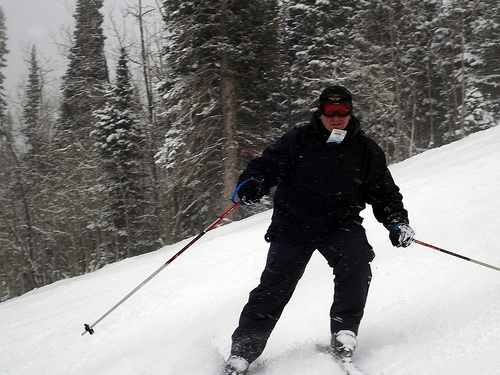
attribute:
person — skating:
[217, 77, 422, 374]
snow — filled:
[0, 122, 498, 373]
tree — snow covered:
[165, 2, 278, 222]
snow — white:
[0, 218, 497, 373]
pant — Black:
[216, 219, 416, 372]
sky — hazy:
[24, 15, 56, 53]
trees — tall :
[0, 2, 497, 304]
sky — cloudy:
[15, 12, 80, 82]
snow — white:
[329, 325, 359, 351]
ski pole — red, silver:
[399, 227, 499, 284]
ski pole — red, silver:
[53, 188, 244, 341]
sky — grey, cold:
[20, 12, 63, 54]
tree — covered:
[88, 45, 160, 275]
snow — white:
[222, 355, 251, 365]